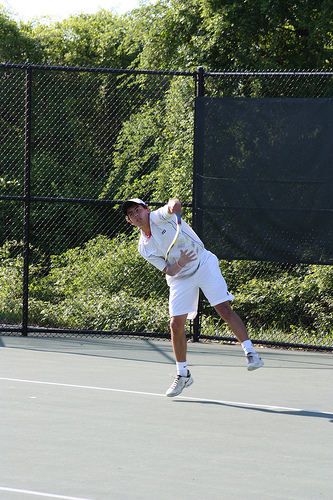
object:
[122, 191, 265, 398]
man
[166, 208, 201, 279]
racket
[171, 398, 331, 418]
shadow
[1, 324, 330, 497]
court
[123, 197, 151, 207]
cap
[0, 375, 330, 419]
lines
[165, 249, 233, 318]
shorts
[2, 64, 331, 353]
fence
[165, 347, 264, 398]
sneakers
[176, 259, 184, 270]
wristband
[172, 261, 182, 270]
right wrist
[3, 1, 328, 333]
trees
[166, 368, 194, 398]
right foot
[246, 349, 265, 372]
left foot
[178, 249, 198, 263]
right hand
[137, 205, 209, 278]
shirt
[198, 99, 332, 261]
fabric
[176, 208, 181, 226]
handle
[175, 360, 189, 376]
sock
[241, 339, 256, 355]
sock